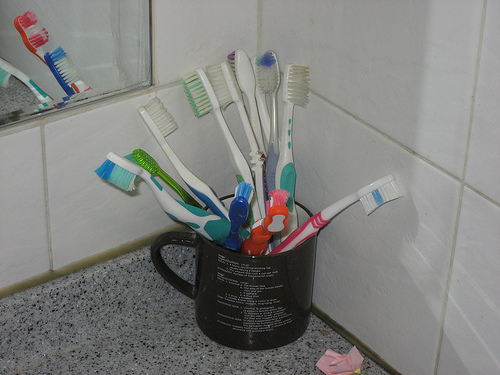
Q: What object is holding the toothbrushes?
A: Coffee cup.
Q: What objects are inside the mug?
A: Toothbrushes.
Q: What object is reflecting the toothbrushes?
A: Mirror.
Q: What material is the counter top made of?
A: Granite.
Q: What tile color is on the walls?
A: White.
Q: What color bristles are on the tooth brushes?
A: White and blue.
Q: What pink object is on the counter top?
A: Paper wrapper.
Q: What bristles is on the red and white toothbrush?
A: Red and white.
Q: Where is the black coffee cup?
A: Bathroom counter.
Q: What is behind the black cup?
A: Mirror.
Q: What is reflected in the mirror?
A: Toothbrushes.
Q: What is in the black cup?
A: Toothbrushes.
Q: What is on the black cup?
A: White writing.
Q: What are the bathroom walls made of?
A: White tiles.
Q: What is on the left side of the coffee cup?
A: Black handle.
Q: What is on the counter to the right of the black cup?
A: Pink paper.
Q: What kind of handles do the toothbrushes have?
A: Multi colored.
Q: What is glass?
A: A mirror.